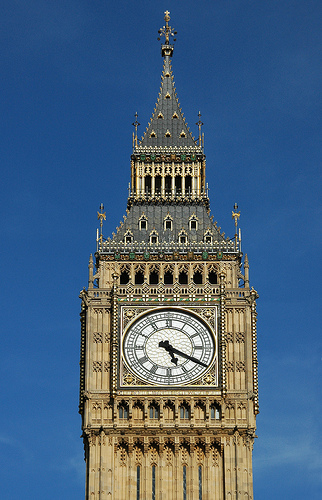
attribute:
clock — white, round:
[116, 302, 223, 386]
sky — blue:
[1, 4, 321, 476]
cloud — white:
[254, 428, 321, 478]